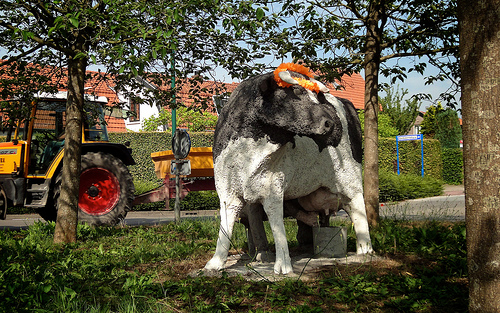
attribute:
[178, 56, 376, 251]
cow — large, wearing, white, black, cement, standing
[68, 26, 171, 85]
tree — behind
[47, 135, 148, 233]
tire — tractor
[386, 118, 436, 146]
sign — blue, backward, road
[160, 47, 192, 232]
pole — tall, white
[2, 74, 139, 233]
tractor — large, yellow, big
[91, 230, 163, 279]
ground — green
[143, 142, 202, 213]
trailer — pulled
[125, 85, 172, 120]
roof — red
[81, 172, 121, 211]
wheel — red, big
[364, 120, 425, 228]
post — blue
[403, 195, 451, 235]
slab — cement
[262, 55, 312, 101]
lei — orange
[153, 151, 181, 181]
box — gold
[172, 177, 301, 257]
front — leg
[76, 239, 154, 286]
grass — green